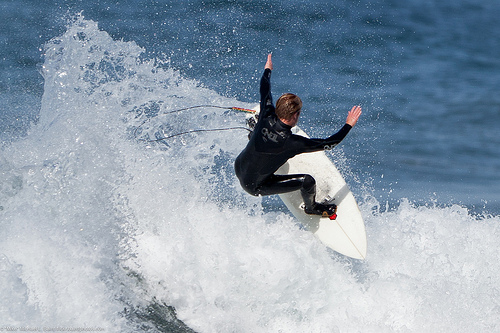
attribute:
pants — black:
[238, 172, 337, 217]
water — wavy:
[315, 37, 477, 158]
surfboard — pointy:
[260, 166, 397, 244]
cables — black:
[149, 101, 256, 143]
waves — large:
[26, 31, 292, 323]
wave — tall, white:
[0, 18, 486, 320]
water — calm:
[367, 75, 467, 151]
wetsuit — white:
[218, 66, 352, 216]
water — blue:
[380, 18, 497, 197]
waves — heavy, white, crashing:
[0, 0, 498, 332]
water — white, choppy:
[27, 36, 227, 298]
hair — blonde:
[274, 94, 302, 121]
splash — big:
[8, 0, 267, 303]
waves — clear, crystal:
[0, 6, 262, 258]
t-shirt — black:
[248, 67, 352, 169]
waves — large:
[90, 183, 305, 330]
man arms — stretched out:
[227, 53, 322, 231]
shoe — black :
[307, 199, 337, 217]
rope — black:
[136, 104, 257, 146]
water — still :
[5, 6, 486, 331]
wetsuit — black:
[239, 122, 317, 206]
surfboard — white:
[236, 103, 382, 268]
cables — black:
[130, 102, 258, 143]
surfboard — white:
[241, 100, 368, 262]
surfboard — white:
[225, 91, 387, 271]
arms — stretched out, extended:
[246, 45, 368, 146]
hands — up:
[261, 47, 364, 130]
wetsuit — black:
[234, 68, 354, 220]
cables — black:
[153, 100, 263, 140]